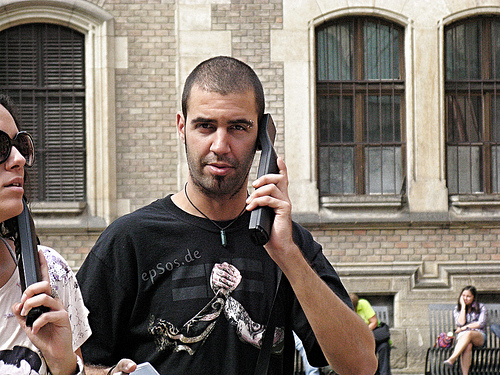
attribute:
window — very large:
[307, 6, 409, 207]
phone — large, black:
[242, 109, 280, 246]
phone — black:
[247, 115, 276, 243]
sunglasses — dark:
[0, 128, 32, 170]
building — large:
[6, 1, 466, 298]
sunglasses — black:
[0, 127, 35, 166]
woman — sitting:
[444, 288, 486, 373]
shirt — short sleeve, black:
[53, 177, 375, 374]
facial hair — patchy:
[183, 129, 255, 200]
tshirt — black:
[93, 195, 363, 354]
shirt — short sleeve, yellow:
[356, 295, 374, 323]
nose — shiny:
[203, 138, 230, 155]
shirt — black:
[72, 186, 354, 373]